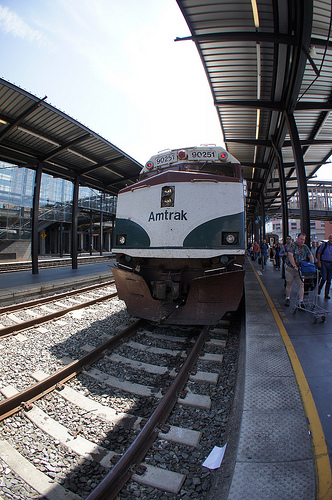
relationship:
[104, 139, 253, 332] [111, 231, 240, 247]
train has headlights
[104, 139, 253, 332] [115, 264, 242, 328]
train has pusher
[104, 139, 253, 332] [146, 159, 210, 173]
train has wipers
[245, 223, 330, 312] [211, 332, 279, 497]
people on platform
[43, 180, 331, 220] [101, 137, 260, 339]
overpass behind train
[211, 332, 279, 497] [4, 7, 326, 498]
platform at train station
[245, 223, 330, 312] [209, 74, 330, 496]
people on train platform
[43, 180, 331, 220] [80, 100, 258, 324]
overpass above train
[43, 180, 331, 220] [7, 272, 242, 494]
overpass above tracks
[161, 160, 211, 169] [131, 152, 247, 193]
windshield wpiers on engine windows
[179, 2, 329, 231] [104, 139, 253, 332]
overhang above train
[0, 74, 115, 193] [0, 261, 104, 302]
shelter over a platform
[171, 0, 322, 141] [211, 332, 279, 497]
shelter over a platform